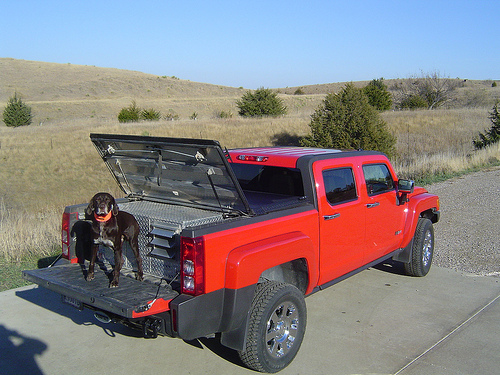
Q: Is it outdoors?
A: Yes, it is outdoors.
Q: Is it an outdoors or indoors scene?
A: It is outdoors.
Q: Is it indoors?
A: No, it is outdoors.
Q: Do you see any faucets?
A: No, there are no faucets.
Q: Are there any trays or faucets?
A: No, there are no faucets or trays.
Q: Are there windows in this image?
A: Yes, there is a window.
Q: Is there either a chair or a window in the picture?
A: Yes, there is a window.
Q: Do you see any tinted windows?
A: Yes, there is a tinted window.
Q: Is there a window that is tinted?
A: Yes, there is a window that is tinted.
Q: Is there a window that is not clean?
A: Yes, there is a tinted window.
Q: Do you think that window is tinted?
A: Yes, the window is tinted.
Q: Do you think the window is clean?
A: No, the window is tinted.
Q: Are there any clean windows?
A: No, there is a window but it is tinted.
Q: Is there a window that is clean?
A: No, there is a window but it is tinted.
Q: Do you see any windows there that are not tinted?
A: No, there is a window but it is tinted.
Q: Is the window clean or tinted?
A: The window is tinted.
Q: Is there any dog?
A: Yes, there is a dog.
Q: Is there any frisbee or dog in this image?
A: Yes, there is a dog.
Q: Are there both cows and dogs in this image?
A: No, there is a dog but no cows.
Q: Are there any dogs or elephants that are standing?
A: Yes, the dog is standing.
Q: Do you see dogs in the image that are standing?
A: Yes, there is a dog that is standing.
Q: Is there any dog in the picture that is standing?
A: Yes, there is a dog that is standing.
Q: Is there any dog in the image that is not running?
A: Yes, there is a dog that is standing.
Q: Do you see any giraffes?
A: No, there are no giraffes.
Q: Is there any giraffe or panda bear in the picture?
A: No, there are no giraffes or panda bears.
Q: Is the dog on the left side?
A: Yes, the dog is on the left of the image.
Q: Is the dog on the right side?
A: No, the dog is on the left of the image.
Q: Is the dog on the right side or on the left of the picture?
A: The dog is on the left of the image.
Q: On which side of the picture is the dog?
A: The dog is on the left of the image.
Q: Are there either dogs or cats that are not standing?
A: No, there is a dog but it is standing.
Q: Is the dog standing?
A: Yes, the dog is standing.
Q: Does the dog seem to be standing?
A: Yes, the dog is standing.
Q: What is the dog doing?
A: The dog is standing.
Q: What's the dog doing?
A: The dog is standing.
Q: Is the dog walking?
A: No, the dog is standing.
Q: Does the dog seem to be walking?
A: No, the dog is standing.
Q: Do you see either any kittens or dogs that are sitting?
A: No, there is a dog but it is standing.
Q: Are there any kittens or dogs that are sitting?
A: No, there is a dog but it is standing.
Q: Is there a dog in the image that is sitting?
A: No, there is a dog but it is standing.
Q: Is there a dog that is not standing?
A: No, there is a dog but it is standing.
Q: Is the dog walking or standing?
A: The dog is standing.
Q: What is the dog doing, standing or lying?
A: The dog is standing.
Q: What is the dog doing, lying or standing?
A: The dog is standing.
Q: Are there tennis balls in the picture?
A: No, there are no tennis balls.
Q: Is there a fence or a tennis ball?
A: No, there are no tennis balls or fences.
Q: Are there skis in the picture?
A: No, there are no skis.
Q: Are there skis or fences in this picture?
A: No, there are no skis or fences.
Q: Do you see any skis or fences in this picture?
A: No, there are no skis or fences.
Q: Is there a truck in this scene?
A: Yes, there is a truck.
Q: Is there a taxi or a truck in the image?
A: Yes, there is a truck.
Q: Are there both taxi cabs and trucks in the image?
A: No, there is a truck but no taxis.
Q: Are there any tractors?
A: No, there are no tractors.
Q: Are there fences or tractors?
A: No, there are no tractors or fences.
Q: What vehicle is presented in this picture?
A: The vehicle is a truck.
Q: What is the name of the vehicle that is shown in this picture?
A: The vehicle is a truck.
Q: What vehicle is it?
A: The vehicle is a truck.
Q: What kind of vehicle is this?
A: This is a truck.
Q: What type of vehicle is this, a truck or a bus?
A: This is a truck.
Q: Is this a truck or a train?
A: This is a truck.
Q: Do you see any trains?
A: No, there are no trains.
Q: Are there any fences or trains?
A: No, there are no trains or fences.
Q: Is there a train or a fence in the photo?
A: No, there are no trains or fences.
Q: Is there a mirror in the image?
A: Yes, there is a mirror.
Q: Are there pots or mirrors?
A: Yes, there is a mirror.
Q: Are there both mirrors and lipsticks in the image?
A: No, there is a mirror but no lipsticks.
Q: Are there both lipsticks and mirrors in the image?
A: No, there is a mirror but no lipsticks.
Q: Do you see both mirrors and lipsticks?
A: No, there is a mirror but no lipsticks.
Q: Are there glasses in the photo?
A: No, there are no glasses.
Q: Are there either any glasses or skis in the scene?
A: No, there are no glasses or skis.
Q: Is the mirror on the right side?
A: Yes, the mirror is on the right of the image.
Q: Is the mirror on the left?
A: No, the mirror is on the right of the image.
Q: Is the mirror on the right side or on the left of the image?
A: The mirror is on the right of the image.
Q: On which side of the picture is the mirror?
A: The mirror is on the right of the image.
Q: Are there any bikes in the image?
A: No, there are no bikes.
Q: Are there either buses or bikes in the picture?
A: No, there are no bikes or buses.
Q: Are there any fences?
A: No, there are no fences.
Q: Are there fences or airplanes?
A: No, there are no fences or airplanes.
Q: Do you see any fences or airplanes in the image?
A: No, there are no fences or airplanes.